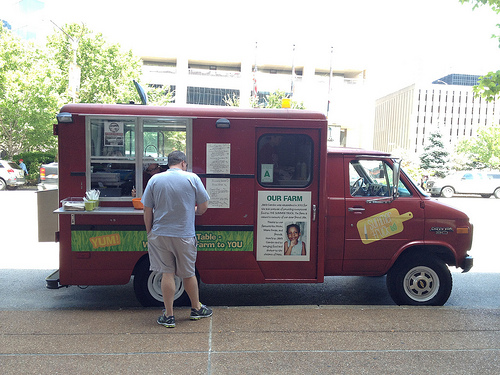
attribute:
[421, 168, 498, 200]
car — white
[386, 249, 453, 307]
wheel — black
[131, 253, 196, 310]
wheel — black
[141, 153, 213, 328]
man — ordering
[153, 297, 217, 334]
shoes — black, white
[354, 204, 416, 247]
sign — yellow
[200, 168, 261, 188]
handle — silver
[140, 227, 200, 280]
pants — grey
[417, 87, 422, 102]
window — glass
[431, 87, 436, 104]
window — glass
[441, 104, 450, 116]
window — glass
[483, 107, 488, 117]
window — glass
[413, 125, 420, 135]
window — glass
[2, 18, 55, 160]
tree — green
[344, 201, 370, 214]
handle — silver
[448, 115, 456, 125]
window — glass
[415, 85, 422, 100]
window — glass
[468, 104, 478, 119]
window — glass